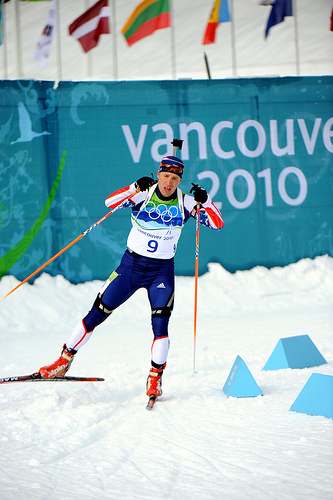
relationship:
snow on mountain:
[62, 391, 253, 457] [30, 130, 309, 381]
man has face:
[35, 154, 223, 401] [160, 156, 204, 218]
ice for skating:
[185, 340, 327, 456] [52, 333, 245, 459]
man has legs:
[35, 154, 223, 401] [57, 290, 290, 409]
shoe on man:
[122, 347, 174, 409] [35, 154, 223, 401]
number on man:
[124, 213, 207, 261] [35, 154, 223, 401]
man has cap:
[35, 154, 223, 401] [140, 126, 209, 183]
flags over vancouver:
[51, 15, 322, 66] [120, 113, 324, 167]